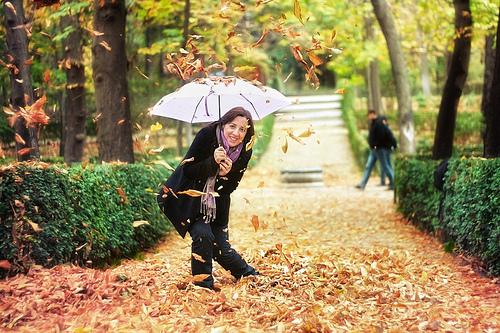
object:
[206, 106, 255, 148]
woman`s head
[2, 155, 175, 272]
bushes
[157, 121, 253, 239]
black coat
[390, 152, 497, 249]
bushes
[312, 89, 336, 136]
ground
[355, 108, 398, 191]
people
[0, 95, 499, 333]
path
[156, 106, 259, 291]
man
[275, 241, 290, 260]
leaf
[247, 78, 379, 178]
bridge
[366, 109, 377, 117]
brown cap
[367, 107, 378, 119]
head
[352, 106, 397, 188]
man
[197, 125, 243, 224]
purple scarf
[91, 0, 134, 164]
tree trunk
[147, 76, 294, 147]
umbrella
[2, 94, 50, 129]
brown leaf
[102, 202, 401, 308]
ground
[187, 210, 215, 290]
legs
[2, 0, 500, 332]
leaves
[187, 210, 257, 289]
pants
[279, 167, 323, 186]
fountain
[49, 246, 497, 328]
dead leaves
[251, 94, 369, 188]
stairs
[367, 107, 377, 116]
hat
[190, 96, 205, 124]
spine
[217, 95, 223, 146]
handle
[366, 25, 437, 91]
air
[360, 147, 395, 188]
jeans